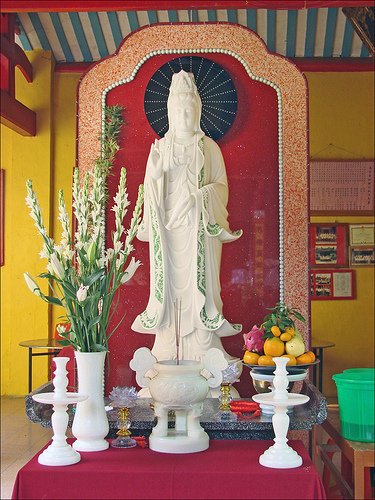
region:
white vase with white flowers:
[68, 163, 125, 448]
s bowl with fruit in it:
[259, 309, 321, 380]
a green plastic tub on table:
[328, 354, 374, 447]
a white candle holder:
[266, 363, 311, 479]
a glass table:
[24, 316, 73, 426]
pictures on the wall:
[309, 218, 373, 317]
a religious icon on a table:
[126, 63, 242, 493]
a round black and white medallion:
[144, 47, 240, 157]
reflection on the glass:
[240, 200, 276, 320]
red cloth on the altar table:
[30, 426, 335, 496]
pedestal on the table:
[257, 360, 306, 474]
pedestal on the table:
[36, 361, 89, 475]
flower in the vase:
[71, 286, 90, 303]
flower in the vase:
[124, 261, 141, 281]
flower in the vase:
[60, 246, 72, 265]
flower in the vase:
[47, 254, 61, 285]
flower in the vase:
[71, 230, 88, 250]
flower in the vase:
[38, 251, 72, 284]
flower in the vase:
[69, 208, 85, 225]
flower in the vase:
[86, 194, 99, 217]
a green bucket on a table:
[332, 370, 366, 415]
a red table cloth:
[87, 459, 293, 493]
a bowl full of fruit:
[250, 315, 306, 384]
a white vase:
[74, 347, 113, 448]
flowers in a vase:
[31, 231, 128, 451]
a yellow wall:
[9, 231, 61, 381]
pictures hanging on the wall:
[313, 233, 354, 289]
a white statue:
[142, 69, 238, 364]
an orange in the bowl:
[268, 335, 281, 349]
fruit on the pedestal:
[263, 338, 285, 356]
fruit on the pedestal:
[287, 340, 304, 353]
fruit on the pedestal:
[257, 358, 271, 367]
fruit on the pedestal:
[241, 351, 257, 361]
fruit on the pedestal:
[249, 332, 264, 355]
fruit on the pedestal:
[301, 355, 311, 361]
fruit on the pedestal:
[280, 353, 292, 364]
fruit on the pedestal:
[277, 329, 290, 340]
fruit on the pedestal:
[274, 327, 283, 336]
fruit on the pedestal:
[304, 350, 315, 359]